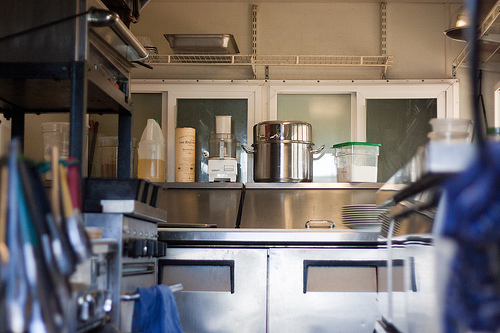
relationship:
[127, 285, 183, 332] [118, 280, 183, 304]
dishcloth on handle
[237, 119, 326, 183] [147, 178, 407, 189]
pot on shelf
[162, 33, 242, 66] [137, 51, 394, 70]
pan on rack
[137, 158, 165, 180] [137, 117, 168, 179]
liquid in bottle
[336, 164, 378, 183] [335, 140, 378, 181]
powder in container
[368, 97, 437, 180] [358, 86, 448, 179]
glass on cabinet door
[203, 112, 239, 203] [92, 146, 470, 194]
mixer on shelf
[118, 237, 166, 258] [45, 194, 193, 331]
knobs on appliance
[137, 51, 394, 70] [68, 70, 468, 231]
rack above cabinets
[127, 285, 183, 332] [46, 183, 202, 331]
dishcloth hanging by stove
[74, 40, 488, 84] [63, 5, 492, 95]
rack on wall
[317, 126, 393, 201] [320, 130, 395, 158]
container has a lid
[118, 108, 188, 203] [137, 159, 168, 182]
bottle contains liquid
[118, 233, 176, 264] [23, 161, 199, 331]
knobs on stove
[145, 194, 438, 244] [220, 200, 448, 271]
lid covering food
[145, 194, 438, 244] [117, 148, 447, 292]
lid on prep counter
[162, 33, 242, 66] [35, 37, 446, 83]
pan on rack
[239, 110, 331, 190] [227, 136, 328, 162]
pot has handles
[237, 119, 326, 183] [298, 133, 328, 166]
pot has handle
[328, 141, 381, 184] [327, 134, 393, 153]
container has lid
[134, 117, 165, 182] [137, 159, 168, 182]
bottle has liquid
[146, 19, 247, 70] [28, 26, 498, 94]
pan on shelf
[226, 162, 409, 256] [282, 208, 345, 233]
drawer has a handle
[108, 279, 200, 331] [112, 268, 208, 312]
dishcloth on a handle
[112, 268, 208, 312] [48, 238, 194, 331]
handle on a oven door